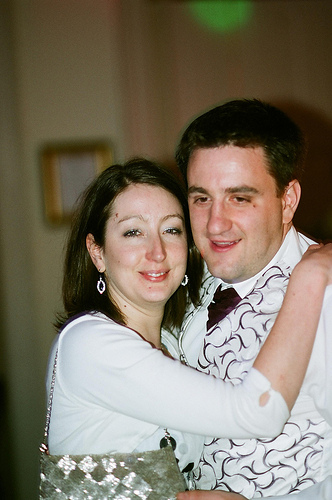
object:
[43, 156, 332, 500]
woman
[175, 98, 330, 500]
man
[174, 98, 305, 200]
hair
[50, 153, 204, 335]
hair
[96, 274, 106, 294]
ear ring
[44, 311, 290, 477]
shirt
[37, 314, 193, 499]
purse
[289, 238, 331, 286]
hand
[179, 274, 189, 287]
ear ring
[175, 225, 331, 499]
vest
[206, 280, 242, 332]
tie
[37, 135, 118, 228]
mirror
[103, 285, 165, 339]
neck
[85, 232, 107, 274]
ear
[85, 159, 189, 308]
head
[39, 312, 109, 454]
strap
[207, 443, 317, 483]
pattern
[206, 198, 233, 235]
nose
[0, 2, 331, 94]
background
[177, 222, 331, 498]
shirt